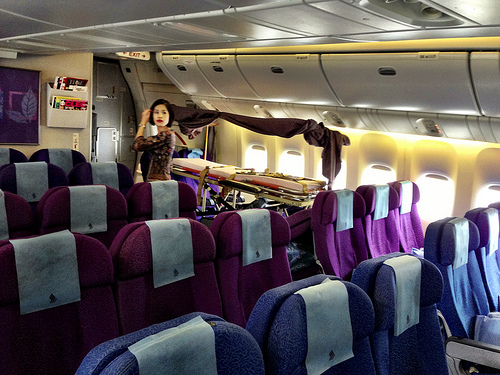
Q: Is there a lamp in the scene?
A: No, there are no lamps.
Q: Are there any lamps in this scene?
A: No, there are no lamps.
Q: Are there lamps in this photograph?
A: No, there are no lamps.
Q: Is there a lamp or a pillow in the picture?
A: No, there are no lamps or pillows.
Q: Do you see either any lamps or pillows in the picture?
A: No, there are no lamps or pillows.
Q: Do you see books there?
A: No, there are no books.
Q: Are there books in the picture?
A: No, there are no books.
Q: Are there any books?
A: No, there are no books.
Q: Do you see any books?
A: No, there are no books.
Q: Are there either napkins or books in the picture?
A: No, there are no books or napkins.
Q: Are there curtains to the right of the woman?
A: Yes, there is a curtain to the right of the woman.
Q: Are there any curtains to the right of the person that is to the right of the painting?
A: Yes, there is a curtain to the right of the woman.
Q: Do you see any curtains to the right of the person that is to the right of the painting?
A: Yes, there is a curtain to the right of the woman.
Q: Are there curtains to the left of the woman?
A: No, the curtain is to the right of the woman.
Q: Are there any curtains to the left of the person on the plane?
A: No, the curtain is to the right of the woman.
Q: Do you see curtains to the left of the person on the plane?
A: No, the curtain is to the right of the woman.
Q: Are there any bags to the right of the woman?
A: No, there is a curtain to the right of the woman.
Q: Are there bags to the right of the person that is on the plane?
A: No, there is a curtain to the right of the woman.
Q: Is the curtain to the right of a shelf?
A: No, the curtain is to the right of the woman.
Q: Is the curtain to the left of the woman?
A: No, the curtain is to the right of the woman.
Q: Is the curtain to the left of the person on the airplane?
A: No, the curtain is to the right of the woman.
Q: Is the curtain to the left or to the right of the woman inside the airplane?
A: The curtain is to the right of the woman.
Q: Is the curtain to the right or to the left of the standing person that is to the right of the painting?
A: The curtain is to the right of the woman.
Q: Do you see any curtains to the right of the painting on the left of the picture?
A: Yes, there is a curtain to the right of the painting.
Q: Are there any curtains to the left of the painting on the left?
A: No, the curtain is to the right of the painting.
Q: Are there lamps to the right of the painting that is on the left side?
A: No, there is a curtain to the right of the painting.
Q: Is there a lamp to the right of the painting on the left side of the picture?
A: No, there is a curtain to the right of the painting.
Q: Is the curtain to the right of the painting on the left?
A: Yes, the curtain is to the right of the painting.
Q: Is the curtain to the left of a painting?
A: No, the curtain is to the right of a painting.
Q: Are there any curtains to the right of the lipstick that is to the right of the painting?
A: Yes, there is a curtain to the right of the lipstick.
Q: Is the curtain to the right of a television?
A: No, the curtain is to the right of the lipstick.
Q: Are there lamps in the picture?
A: No, there are no lamps.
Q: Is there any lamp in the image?
A: No, there are no lamps.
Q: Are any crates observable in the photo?
A: No, there are no crates.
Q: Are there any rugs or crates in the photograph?
A: No, there are no crates or rugs.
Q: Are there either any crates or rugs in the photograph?
A: No, there are no crates or rugs.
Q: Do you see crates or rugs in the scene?
A: No, there are no crates or rugs.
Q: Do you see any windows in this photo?
A: Yes, there are windows.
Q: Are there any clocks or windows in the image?
A: Yes, there are windows.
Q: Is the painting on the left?
A: Yes, the painting is on the left of the image.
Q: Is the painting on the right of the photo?
A: No, the painting is on the left of the image.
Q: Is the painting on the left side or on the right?
A: The painting is on the left of the image.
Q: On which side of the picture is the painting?
A: The painting is on the left of the image.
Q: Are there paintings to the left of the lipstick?
A: Yes, there is a painting to the left of the lipstick.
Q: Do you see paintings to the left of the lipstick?
A: Yes, there is a painting to the left of the lipstick.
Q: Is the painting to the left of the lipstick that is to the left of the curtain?
A: Yes, the painting is to the left of the lipstick.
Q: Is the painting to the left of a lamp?
A: No, the painting is to the left of the lipstick.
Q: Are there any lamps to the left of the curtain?
A: No, there is a painting to the left of the curtain.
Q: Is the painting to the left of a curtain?
A: Yes, the painting is to the left of a curtain.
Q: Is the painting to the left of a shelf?
A: No, the painting is to the left of a curtain.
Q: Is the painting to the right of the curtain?
A: No, the painting is to the left of the curtain.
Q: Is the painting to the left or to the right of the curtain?
A: The painting is to the left of the curtain.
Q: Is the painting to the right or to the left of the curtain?
A: The painting is to the left of the curtain.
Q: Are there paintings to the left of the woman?
A: Yes, there is a painting to the left of the woman.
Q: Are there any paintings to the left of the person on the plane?
A: Yes, there is a painting to the left of the woman.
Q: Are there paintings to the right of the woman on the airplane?
A: No, the painting is to the left of the woman.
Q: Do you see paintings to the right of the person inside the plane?
A: No, the painting is to the left of the woman.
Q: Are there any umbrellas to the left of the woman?
A: No, there is a painting to the left of the woman.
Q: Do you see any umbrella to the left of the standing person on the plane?
A: No, there is a painting to the left of the woman.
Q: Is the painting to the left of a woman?
A: Yes, the painting is to the left of a woman.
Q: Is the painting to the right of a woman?
A: No, the painting is to the left of a woman.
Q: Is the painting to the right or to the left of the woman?
A: The painting is to the left of the woman.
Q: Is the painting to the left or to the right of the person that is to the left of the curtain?
A: The painting is to the left of the woman.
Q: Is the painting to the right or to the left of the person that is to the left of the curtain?
A: The painting is to the left of the woman.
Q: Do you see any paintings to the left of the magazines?
A: Yes, there is a painting to the left of the magazines.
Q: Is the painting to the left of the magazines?
A: Yes, the painting is to the left of the magazines.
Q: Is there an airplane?
A: Yes, there is an airplane.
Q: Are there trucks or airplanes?
A: Yes, there is an airplane.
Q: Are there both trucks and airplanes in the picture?
A: No, there is an airplane but no trucks.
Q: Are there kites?
A: No, there are no kites.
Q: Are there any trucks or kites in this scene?
A: No, there are no kites or trucks.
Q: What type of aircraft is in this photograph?
A: The aircraft is an airplane.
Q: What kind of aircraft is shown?
A: The aircraft is an airplane.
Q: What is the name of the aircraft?
A: The aircraft is an airplane.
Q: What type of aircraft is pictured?
A: The aircraft is an airplane.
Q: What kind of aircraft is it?
A: The aircraft is an airplane.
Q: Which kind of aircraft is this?
A: This is an airplane.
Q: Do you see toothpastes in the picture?
A: No, there are no toothpastes.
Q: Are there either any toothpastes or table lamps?
A: No, there are no toothpastes or table lamps.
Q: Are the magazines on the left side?
A: Yes, the magazines are on the left of the image.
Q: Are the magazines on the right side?
A: No, the magazines are on the left of the image.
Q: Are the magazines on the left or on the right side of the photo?
A: The magazines are on the left of the image.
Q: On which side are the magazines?
A: The magazines are on the left of the image.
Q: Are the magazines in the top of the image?
A: Yes, the magazines are in the top of the image.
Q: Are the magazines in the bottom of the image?
A: No, the magazines are in the top of the image.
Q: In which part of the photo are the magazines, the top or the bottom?
A: The magazines are in the top of the image.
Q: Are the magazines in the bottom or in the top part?
A: The magazines are in the top of the image.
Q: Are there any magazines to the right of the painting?
A: Yes, there are magazines to the right of the painting.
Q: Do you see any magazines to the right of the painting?
A: Yes, there are magazines to the right of the painting.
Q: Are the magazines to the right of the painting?
A: Yes, the magazines are to the right of the painting.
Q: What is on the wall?
A: The magazines are on the wall.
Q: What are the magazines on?
A: The magazines are on the wall.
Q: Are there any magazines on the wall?
A: Yes, there are magazines on the wall.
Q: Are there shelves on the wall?
A: No, there are magazines on the wall.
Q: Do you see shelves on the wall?
A: No, there are magazines on the wall.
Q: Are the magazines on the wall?
A: Yes, the magazines are on the wall.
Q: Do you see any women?
A: Yes, there is a woman.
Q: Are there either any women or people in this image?
A: Yes, there is a woman.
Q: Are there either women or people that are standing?
A: Yes, the woman is standing.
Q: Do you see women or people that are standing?
A: Yes, the woman is standing.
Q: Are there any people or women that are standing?
A: Yes, the woman is standing.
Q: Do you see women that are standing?
A: Yes, there is a woman that is standing.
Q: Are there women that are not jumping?
A: Yes, there is a woman that is standing.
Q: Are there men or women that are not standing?
A: No, there is a woman but she is standing.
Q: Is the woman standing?
A: Yes, the woman is standing.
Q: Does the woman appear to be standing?
A: Yes, the woman is standing.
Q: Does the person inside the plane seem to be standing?
A: Yes, the woman is standing.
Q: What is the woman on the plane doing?
A: The woman is standing.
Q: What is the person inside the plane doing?
A: The woman is standing.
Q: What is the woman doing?
A: The woman is standing.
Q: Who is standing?
A: The woman is standing.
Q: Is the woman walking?
A: No, the woman is standing.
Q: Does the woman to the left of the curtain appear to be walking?
A: No, the woman is standing.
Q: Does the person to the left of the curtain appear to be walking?
A: No, the woman is standing.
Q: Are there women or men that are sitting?
A: No, there is a woman but she is standing.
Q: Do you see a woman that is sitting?
A: No, there is a woman but she is standing.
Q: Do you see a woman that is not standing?
A: No, there is a woman but she is standing.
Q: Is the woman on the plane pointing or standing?
A: The woman is standing.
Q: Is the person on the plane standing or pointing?
A: The woman is standing.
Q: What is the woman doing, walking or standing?
A: The woman is standing.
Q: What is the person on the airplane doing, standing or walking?
A: The woman is standing.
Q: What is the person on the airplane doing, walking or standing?
A: The woman is standing.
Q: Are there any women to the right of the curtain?
A: No, the woman is to the left of the curtain.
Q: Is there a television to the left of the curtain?
A: No, there is a woman to the left of the curtain.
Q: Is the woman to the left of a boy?
A: No, the woman is to the left of the curtain.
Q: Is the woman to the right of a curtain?
A: No, the woman is to the left of a curtain.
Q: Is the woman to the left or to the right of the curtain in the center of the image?
A: The woman is to the left of the curtain.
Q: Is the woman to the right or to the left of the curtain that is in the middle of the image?
A: The woman is to the left of the curtain.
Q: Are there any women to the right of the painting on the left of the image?
A: Yes, there is a woman to the right of the painting.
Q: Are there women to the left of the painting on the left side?
A: No, the woman is to the right of the painting.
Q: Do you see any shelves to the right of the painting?
A: No, there is a woman to the right of the painting.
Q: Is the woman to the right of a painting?
A: Yes, the woman is to the right of a painting.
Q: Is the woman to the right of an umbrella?
A: No, the woman is to the right of a painting.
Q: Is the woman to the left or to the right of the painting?
A: The woman is to the right of the painting.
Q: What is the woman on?
A: The woman is on the airplane.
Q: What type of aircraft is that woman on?
A: The woman is on the plane.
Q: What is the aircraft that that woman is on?
A: The aircraft is an airplane.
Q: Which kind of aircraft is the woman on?
A: The woman is on the plane.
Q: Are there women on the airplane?
A: Yes, there is a woman on the airplane.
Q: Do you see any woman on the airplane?
A: Yes, there is a woman on the airplane.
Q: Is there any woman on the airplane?
A: Yes, there is a woman on the airplane.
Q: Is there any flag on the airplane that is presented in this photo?
A: No, there is a woman on the airplane.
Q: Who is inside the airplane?
A: The woman is inside the airplane.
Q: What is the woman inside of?
A: The woman is inside the plane.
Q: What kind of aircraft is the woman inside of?
A: The woman is inside the airplane.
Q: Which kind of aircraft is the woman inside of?
A: The woman is inside the airplane.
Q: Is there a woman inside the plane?
A: Yes, there is a woman inside the plane.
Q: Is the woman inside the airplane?
A: Yes, the woman is inside the airplane.